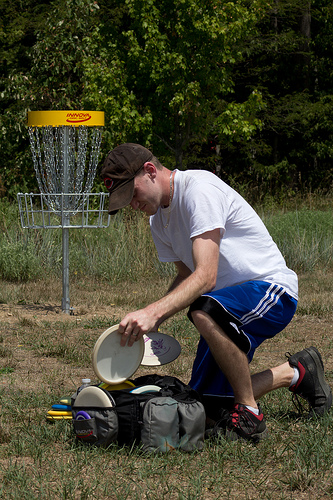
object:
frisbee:
[91, 323, 144, 386]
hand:
[117, 303, 159, 350]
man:
[101, 142, 333, 445]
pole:
[60, 181, 70, 311]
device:
[18, 109, 112, 311]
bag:
[70, 373, 206, 454]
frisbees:
[73, 384, 116, 409]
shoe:
[205, 398, 270, 445]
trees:
[140, 0, 333, 177]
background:
[0, 0, 332, 191]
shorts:
[186, 278, 298, 406]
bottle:
[79, 378, 92, 392]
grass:
[0, 204, 333, 499]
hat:
[99, 142, 154, 216]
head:
[100, 141, 164, 216]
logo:
[76, 427, 94, 439]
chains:
[59, 125, 103, 217]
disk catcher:
[26, 110, 105, 129]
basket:
[18, 192, 114, 229]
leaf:
[86, 64, 94, 73]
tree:
[0, 0, 157, 188]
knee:
[190, 298, 216, 337]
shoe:
[287, 346, 333, 426]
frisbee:
[46, 410, 73, 422]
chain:
[25, 124, 60, 210]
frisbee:
[51, 402, 72, 412]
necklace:
[159, 170, 174, 229]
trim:
[191, 295, 252, 355]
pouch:
[141, 396, 179, 458]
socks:
[290, 367, 300, 387]